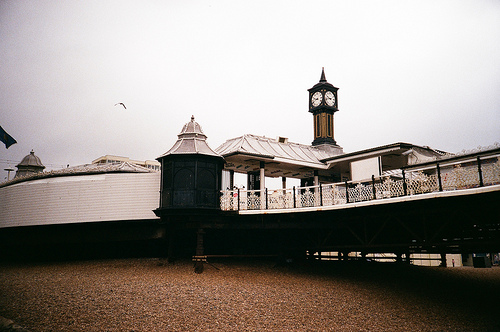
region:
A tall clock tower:
[305, 66, 345, 149]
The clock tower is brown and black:
[307, 58, 352, 160]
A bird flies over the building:
[103, 92, 133, 114]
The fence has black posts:
[225, 150, 485, 210]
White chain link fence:
[221, 161, 483, 216]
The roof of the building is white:
[158, 92, 380, 170]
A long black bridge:
[218, 169, 485, 256]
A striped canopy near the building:
[383, 165, 430, 186]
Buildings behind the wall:
[21, 150, 164, 182]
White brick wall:
[8, 170, 170, 245]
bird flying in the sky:
[105, 96, 132, 115]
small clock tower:
[301, 58, 346, 145]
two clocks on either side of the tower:
[301, 83, 341, 112]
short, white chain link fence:
[221, 160, 499, 213]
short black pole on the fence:
[367, 168, 382, 201]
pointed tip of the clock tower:
[318, 61, 329, 78]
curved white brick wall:
[0, 171, 160, 236]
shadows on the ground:
[253, 261, 495, 324]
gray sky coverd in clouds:
[2, 3, 499, 169]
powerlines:
[1, 160, 17, 180]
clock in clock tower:
[320, 88, 336, 110]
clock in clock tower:
[308, 88, 319, 109]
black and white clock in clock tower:
[306, 89, 320, 107]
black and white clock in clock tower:
[324, 88, 334, 108]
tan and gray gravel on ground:
[57, 272, 187, 313]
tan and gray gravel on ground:
[237, 275, 307, 320]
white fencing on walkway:
[352, 185, 378, 199]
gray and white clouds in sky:
[37, 22, 160, 88]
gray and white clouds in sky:
[218, 13, 360, 70]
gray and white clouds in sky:
[369, 17, 443, 101]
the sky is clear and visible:
[97, 81, 258, 170]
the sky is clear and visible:
[51, 61, 268, 267]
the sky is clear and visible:
[38, 1, 203, 165]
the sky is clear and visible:
[85, 8, 318, 322]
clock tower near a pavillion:
[297, 60, 353, 141]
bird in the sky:
[108, 92, 133, 119]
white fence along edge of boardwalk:
[240, 168, 405, 209]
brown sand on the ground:
[53, 278, 395, 325]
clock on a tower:
[324, 89, 337, 109]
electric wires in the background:
[0, 152, 17, 169]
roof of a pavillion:
[219, 131, 334, 178]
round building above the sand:
[2, 170, 161, 230]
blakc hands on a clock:
[325, 93, 334, 101]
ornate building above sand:
[152, 108, 231, 219]